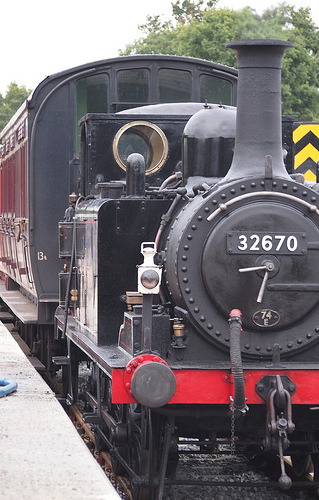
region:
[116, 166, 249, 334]
A train in the photo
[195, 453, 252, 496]
Track ballast in the photo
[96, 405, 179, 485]
Wheels of the train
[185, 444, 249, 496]
A railway track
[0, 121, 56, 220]
Red paint on the train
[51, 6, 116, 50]
Clouds in the skies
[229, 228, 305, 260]
Numbers on the train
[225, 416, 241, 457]
A chain on the train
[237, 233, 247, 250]
white number on train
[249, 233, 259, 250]
white number on train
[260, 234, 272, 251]
white number on train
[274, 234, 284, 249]
white number on train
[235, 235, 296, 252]
the numbers are white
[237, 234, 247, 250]
A number on a train.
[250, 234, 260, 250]
A number on a train.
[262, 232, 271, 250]
A number on a train.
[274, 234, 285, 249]
A number on a train.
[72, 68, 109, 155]
A window on a train.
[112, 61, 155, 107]
A window on a train.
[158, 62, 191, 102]
A window on a train.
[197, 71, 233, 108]
A window on a train.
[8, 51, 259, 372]
A train car on a track.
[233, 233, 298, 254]
a large number written in white on the front of the train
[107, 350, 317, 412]
red part on the front of the train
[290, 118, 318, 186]
a yellow and black sign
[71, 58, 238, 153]
windows on the front of the train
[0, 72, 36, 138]
trees behind the train and to the left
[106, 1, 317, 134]
trees behind the train and to the right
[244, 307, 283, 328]
an oval metal sign with the number 74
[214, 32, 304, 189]
smoke stack on the front of the train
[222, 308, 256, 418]
a black hose on the front of the train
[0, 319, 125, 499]
train station platform beside the train